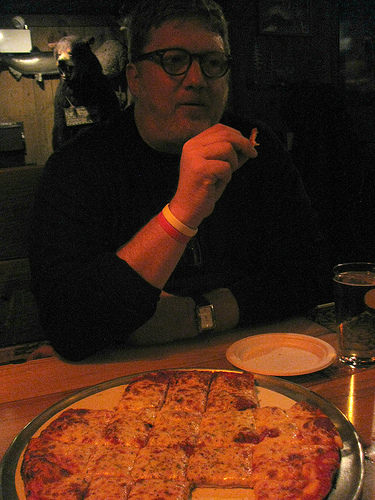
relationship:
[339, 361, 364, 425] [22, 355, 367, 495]
light reflected on table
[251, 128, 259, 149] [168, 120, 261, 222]
food in hand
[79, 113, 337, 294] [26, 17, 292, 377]
arm of person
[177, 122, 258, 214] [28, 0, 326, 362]
hand of man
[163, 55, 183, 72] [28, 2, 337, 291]
eye of person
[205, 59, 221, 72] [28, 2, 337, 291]
eye of person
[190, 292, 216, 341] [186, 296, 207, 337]
watch on wrist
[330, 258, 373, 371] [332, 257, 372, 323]
glass with liquid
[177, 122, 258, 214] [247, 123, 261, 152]
hand holding food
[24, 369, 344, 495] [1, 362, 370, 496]
pizza on platter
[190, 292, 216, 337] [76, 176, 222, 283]
watch on arm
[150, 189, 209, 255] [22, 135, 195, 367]
bracelet on arm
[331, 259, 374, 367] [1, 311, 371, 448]
cup on table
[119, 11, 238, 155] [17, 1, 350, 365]
head of person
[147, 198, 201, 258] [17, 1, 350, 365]
wrist of person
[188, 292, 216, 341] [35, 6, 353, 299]
arm of person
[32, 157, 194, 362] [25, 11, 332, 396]
arm of person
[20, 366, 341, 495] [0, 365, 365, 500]
snacks on platter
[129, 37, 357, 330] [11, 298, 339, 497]
man leaning on table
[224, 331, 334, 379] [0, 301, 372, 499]
plate on table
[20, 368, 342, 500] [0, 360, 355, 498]
pizza on tray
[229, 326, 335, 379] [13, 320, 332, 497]
plate on table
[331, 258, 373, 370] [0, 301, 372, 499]
glass on table